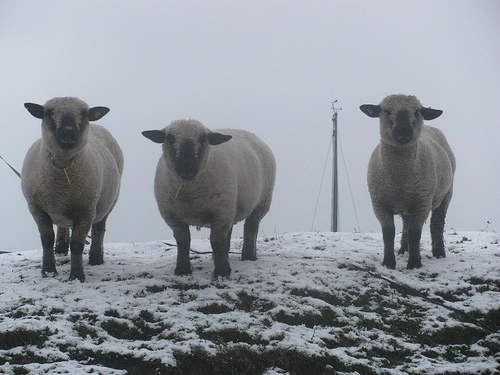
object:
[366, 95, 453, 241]
fur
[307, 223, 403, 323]
snowy plants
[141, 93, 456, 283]
sheep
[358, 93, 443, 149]
raised head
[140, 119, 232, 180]
lowered head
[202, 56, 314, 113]
wall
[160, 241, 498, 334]
cable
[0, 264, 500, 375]
grass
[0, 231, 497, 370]
grass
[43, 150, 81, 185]
collar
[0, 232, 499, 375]
snow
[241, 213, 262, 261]
leg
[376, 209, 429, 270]
legs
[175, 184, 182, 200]
yellow tag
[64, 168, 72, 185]
yellow tag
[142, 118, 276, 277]
fur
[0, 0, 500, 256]
sky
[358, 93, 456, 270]
animal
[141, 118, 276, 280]
animal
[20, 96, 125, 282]
animal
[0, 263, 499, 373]
ground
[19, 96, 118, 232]
fur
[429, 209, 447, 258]
leg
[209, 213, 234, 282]
leg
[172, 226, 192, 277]
leg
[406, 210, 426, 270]
leg